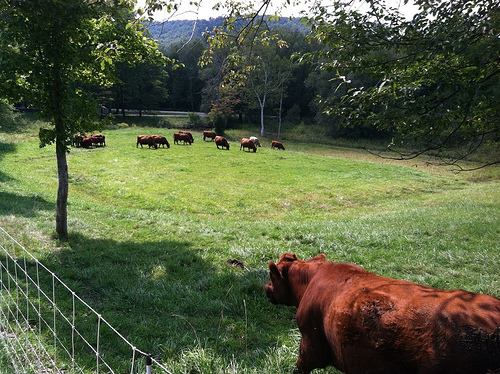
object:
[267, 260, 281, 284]
ear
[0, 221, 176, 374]
fence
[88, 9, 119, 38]
leaves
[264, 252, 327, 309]
head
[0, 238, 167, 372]
wire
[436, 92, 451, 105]
leaves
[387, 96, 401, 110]
leaves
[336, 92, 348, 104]
leaves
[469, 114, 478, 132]
leaves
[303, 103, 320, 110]
leaves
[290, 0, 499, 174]
tree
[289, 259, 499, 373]
brown fur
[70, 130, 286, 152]
animals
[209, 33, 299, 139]
tree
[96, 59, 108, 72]
leaf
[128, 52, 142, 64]
leaf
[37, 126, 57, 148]
leaf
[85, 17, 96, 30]
leaf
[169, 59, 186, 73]
leaf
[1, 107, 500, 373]
grass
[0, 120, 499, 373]
bench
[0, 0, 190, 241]
tree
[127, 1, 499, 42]
sky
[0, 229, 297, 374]
shadow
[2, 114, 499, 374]
ground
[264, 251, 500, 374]
animal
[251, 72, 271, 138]
trunk